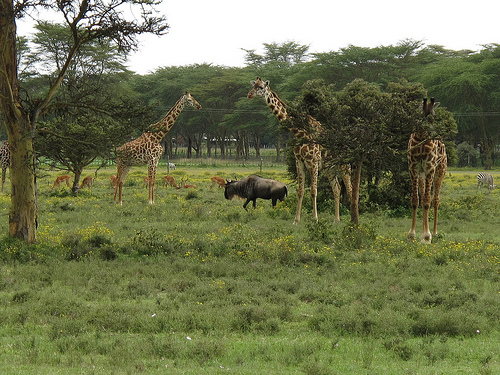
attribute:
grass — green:
[3, 149, 498, 374]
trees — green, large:
[0, 17, 498, 162]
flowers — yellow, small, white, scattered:
[1, 219, 497, 273]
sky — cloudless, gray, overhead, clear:
[13, 1, 500, 80]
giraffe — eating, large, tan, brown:
[406, 97, 446, 246]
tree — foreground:
[1, 0, 171, 241]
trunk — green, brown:
[0, 0, 40, 247]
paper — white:
[185, 334, 193, 343]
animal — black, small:
[222, 173, 292, 213]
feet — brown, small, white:
[407, 227, 439, 245]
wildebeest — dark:
[222, 173, 290, 211]